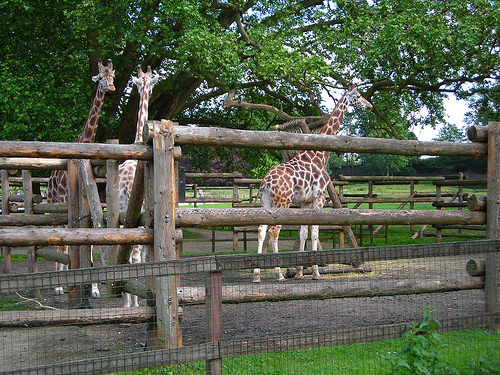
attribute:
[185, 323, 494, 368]
lawn — healthy, wide, green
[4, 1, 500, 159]
tree — big, large, tall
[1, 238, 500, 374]
net — mesh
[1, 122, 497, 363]
fence — wooden, wood, large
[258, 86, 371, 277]
giraffe — tall, all alone, single, grazing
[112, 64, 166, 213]
giraffe — tall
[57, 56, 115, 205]
giraffe — in park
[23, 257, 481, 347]
dirt — large, brown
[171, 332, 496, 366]
grass — small, green